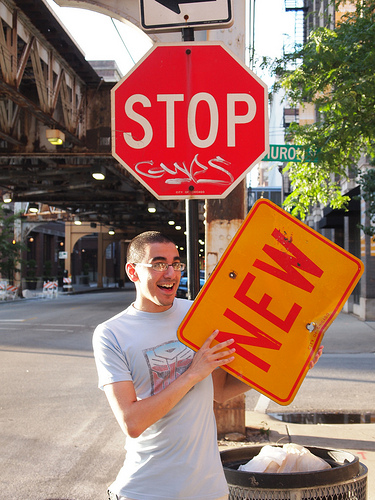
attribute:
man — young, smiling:
[92, 231, 324, 498]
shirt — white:
[93, 297, 231, 499]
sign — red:
[110, 41, 270, 201]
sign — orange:
[177, 198, 365, 407]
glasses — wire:
[127, 263, 185, 273]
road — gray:
[0, 282, 374, 498]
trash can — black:
[220, 446, 369, 499]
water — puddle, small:
[266, 410, 374, 426]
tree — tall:
[245, 0, 374, 242]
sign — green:
[260, 146, 320, 166]